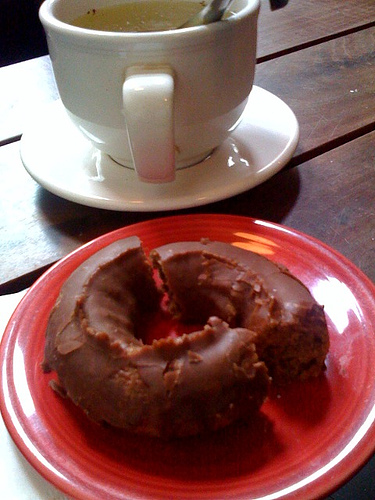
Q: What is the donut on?
A: Red plate.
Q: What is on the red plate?
A: Donut.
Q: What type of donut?
A: Chocolate.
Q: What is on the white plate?
A: White cup.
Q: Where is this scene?
A: It is outdoors.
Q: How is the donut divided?
A: In half.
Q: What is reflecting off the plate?
A: Light.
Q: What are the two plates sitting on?
A: Wood table.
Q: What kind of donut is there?
A: Chocolate.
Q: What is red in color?
A: The plate.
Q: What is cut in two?
A: The donut.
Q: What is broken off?
A: Piece of donut.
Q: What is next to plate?
A: A cup.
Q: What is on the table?
A: Lines.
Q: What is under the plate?
A: The table.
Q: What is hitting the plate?
A: Light.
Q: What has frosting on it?
A: The donut.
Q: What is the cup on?
A: A plate.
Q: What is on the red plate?
A: A donut.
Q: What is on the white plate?
A: A cup.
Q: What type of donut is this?
A: Chocolate.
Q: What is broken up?
A: The donut.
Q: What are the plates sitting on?
A: A wooden table.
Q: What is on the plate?
A: Donut.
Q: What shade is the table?
A: Brown.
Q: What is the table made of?
A: Wood.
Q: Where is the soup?
A: Cup.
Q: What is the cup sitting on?
A: Saucer.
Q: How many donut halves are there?
A: Two.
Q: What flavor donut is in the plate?
A: Chocolate.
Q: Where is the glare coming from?
A: Window.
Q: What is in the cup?
A: Spoon.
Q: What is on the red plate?
A: A doughnut.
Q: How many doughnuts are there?
A: 1.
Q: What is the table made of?
A: Wood.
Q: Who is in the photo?
A: No one.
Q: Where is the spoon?
A: In the cup.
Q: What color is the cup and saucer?
A: White.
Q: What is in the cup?
A: Tea.